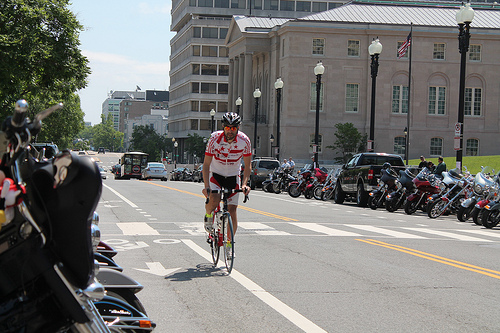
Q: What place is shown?
A: It is a street.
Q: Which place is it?
A: It is a street.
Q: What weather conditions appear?
A: It is sunny.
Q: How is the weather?
A: It is sunny.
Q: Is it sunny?
A: Yes, it is sunny.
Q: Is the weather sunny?
A: Yes, it is sunny.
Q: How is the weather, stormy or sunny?
A: It is sunny.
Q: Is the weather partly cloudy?
A: No, it is sunny.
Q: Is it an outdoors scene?
A: Yes, it is outdoors.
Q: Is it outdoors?
A: Yes, it is outdoors.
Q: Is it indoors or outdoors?
A: It is outdoors.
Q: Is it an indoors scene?
A: No, it is outdoors.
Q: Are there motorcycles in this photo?
A: Yes, there are motorcycles.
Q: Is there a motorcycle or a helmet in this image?
A: Yes, there are motorcycles.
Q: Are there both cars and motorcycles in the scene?
A: Yes, there are both motorcycles and a car.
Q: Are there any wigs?
A: No, there are no wigs.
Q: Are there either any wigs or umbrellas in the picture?
A: No, there are no wigs or umbrellas.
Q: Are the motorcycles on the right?
A: Yes, the motorcycles are on the right of the image.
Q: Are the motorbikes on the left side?
A: No, the motorbikes are on the right of the image.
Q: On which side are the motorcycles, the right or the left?
A: The motorcycles are on the right of the image.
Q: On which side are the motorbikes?
A: The motorbikes are on the right of the image.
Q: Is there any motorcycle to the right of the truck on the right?
A: Yes, there are motorcycles to the right of the truck.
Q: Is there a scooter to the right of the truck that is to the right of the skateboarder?
A: No, there are motorcycles to the right of the truck.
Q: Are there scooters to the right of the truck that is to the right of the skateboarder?
A: No, there are motorcycles to the right of the truck.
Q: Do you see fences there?
A: No, there are no fences.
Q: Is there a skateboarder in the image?
A: Yes, there is a skateboarder.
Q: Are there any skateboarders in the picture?
A: Yes, there is a skateboarder.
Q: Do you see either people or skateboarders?
A: Yes, there is a skateboarder.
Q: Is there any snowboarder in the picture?
A: No, there are no snowboarders.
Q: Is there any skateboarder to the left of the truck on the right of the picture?
A: Yes, there is a skateboarder to the left of the truck.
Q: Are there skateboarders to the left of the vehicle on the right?
A: Yes, there is a skateboarder to the left of the truck.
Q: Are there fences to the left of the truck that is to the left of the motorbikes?
A: No, there is a skateboarder to the left of the truck.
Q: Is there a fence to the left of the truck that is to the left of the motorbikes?
A: No, there is a skateboarder to the left of the truck.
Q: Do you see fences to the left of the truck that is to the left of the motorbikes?
A: No, there is a skateboarder to the left of the truck.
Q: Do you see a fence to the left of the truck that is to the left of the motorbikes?
A: No, there is a skateboarder to the left of the truck.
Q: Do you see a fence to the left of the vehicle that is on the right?
A: No, there is a skateboarder to the left of the truck.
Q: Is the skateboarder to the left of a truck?
A: Yes, the skateboarder is to the left of a truck.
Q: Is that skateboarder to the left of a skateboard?
A: No, the skateboarder is to the left of a truck.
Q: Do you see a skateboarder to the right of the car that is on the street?
A: Yes, there is a skateboarder to the right of the car.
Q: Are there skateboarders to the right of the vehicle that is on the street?
A: Yes, there is a skateboarder to the right of the car.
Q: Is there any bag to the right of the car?
A: No, there is a skateboarder to the right of the car.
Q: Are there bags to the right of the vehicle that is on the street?
A: No, there is a skateboarder to the right of the car.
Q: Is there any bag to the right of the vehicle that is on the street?
A: No, there is a skateboarder to the right of the car.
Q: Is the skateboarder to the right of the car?
A: Yes, the skateboarder is to the right of the car.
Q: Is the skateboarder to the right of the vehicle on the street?
A: Yes, the skateboarder is to the right of the car.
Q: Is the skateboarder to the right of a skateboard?
A: No, the skateboarder is to the right of the car.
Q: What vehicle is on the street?
A: The vehicle is a car.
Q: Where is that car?
A: The car is on the street.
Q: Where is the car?
A: The car is on the street.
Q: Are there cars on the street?
A: Yes, there is a car on the street.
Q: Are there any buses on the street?
A: No, there is a car on the street.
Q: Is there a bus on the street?
A: No, there is a car on the street.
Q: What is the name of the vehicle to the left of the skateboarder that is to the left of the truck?
A: The vehicle is a car.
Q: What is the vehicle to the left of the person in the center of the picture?
A: The vehicle is a car.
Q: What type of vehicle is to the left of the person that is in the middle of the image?
A: The vehicle is a car.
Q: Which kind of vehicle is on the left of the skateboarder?
A: The vehicle is a car.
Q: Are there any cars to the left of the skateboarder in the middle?
A: Yes, there is a car to the left of the skateboarder.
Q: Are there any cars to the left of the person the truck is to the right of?
A: Yes, there is a car to the left of the skateboarder.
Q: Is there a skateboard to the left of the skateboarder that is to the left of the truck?
A: No, there is a car to the left of the skateboarder.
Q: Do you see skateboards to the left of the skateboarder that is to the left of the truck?
A: No, there is a car to the left of the skateboarder.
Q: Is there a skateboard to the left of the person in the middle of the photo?
A: No, there is a car to the left of the skateboarder.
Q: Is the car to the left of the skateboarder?
A: Yes, the car is to the left of the skateboarder.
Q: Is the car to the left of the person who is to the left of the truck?
A: Yes, the car is to the left of the skateboarder.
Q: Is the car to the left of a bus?
A: No, the car is to the left of the skateboarder.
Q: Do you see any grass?
A: Yes, there is grass.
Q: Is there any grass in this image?
A: Yes, there is grass.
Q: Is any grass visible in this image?
A: Yes, there is grass.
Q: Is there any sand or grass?
A: Yes, there is grass.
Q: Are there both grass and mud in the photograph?
A: No, there is grass but no mud.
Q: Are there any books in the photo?
A: No, there are no books.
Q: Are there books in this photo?
A: No, there are no books.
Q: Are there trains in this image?
A: Yes, there is a train.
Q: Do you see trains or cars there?
A: Yes, there is a train.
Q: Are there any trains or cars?
A: Yes, there is a train.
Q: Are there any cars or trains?
A: Yes, there is a train.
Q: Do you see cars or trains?
A: Yes, there is a train.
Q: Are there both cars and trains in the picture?
A: Yes, there are both a train and cars.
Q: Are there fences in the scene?
A: No, there are no fences.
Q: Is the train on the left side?
A: Yes, the train is on the left of the image.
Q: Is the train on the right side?
A: No, the train is on the left of the image.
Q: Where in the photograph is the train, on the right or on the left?
A: The train is on the left of the image.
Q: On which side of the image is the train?
A: The train is on the left of the image.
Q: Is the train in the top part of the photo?
A: Yes, the train is in the top of the image.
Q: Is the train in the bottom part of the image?
A: No, the train is in the top of the image.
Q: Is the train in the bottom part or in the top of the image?
A: The train is in the top of the image.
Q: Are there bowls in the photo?
A: No, there are no bowls.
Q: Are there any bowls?
A: No, there are no bowls.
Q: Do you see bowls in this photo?
A: No, there are no bowls.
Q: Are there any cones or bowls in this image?
A: No, there are no bowls or cones.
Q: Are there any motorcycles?
A: Yes, there is a motorcycle.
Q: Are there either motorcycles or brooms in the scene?
A: Yes, there is a motorcycle.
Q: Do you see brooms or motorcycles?
A: Yes, there is a motorcycle.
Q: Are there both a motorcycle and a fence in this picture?
A: No, there is a motorcycle but no fences.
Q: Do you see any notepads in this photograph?
A: No, there are no notepads.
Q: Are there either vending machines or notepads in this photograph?
A: No, there are no notepads or vending machines.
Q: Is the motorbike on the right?
A: Yes, the motorbike is on the right of the image.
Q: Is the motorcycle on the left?
A: No, the motorcycle is on the right of the image.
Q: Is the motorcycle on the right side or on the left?
A: The motorcycle is on the right of the image.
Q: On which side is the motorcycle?
A: The motorcycle is on the right of the image.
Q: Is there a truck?
A: Yes, there is a truck.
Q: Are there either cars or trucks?
A: Yes, there is a truck.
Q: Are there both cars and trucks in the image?
A: Yes, there are both a truck and cars.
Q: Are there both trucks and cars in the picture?
A: Yes, there are both a truck and cars.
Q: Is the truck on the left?
A: No, the truck is on the right of the image.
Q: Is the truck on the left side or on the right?
A: The truck is on the right of the image.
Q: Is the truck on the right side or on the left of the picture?
A: The truck is on the right of the image.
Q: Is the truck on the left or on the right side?
A: The truck is on the right of the image.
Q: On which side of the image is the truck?
A: The truck is on the right of the image.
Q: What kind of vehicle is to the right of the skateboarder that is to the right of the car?
A: The vehicle is a truck.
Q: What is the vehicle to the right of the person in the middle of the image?
A: The vehicle is a truck.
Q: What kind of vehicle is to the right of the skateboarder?
A: The vehicle is a truck.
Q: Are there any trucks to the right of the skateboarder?
A: Yes, there is a truck to the right of the skateboarder.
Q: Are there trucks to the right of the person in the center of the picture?
A: Yes, there is a truck to the right of the skateboarder.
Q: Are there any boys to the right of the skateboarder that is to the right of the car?
A: No, there is a truck to the right of the skateboarder.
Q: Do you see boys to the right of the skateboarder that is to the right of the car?
A: No, there is a truck to the right of the skateboarder.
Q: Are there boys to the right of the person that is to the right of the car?
A: No, there is a truck to the right of the skateboarder.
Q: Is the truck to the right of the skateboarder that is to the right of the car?
A: Yes, the truck is to the right of the skateboarder.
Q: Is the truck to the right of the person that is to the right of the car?
A: Yes, the truck is to the right of the skateboarder.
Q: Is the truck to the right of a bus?
A: No, the truck is to the right of the skateboarder.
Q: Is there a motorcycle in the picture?
A: Yes, there are motorcycles.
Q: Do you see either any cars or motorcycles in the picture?
A: Yes, there are motorcycles.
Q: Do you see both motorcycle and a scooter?
A: No, there are motorcycles but no scooters.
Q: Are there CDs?
A: No, there are no cds.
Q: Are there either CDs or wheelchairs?
A: No, there are no CDs or wheelchairs.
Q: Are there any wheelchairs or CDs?
A: No, there are no CDs or wheelchairs.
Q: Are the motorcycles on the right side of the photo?
A: Yes, the motorcycles are on the right of the image.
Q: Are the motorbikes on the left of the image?
A: No, the motorbikes are on the right of the image.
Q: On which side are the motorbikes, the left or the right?
A: The motorbikes are on the right of the image.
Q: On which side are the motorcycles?
A: The motorcycles are on the right of the image.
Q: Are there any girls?
A: No, there are no girls.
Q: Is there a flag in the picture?
A: Yes, there is a flag.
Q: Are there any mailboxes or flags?
A: Yes, there is a flag.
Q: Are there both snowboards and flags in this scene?
A: No, there is a flag but no snowboards.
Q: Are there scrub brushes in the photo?
A: No, there are no scrub brushes.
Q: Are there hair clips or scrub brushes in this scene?
A: No, there are no scrub brushes or hair clips.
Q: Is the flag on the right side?
A: Yes, the flag is on the right of the image.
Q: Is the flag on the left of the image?
A: No, the flag is on the right of the image.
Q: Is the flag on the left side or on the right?
A: The flag is on the right of the image.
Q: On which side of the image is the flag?
A: The flag is on the right of the image.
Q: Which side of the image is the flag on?
A: The flag is on the right of the image.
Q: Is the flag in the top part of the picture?
A: Yes, the flag is in the top of the image.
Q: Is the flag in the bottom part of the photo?
A: No, the flag is in the top of the image.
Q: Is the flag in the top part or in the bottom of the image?
A: The flag is in the top of the image.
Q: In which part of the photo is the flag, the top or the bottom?
A: The flag is in the top of the image.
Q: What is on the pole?
A: The flag is on the pole.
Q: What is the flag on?
A: The flag is on the pole.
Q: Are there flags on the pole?
A: Yes, there is a flag on the pole.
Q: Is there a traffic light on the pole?
A: No, there is a flag on the pole.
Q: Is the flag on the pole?
A: Yes, the flag is on the pole.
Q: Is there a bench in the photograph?
A: No, there are no benches.